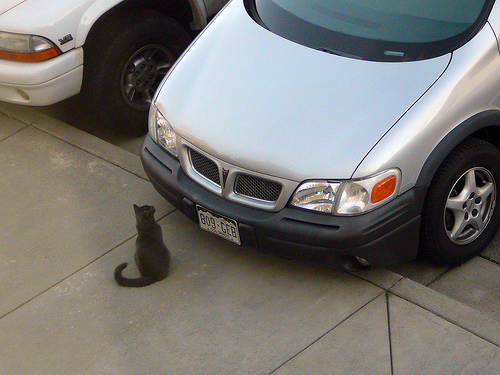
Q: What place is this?
A: It is a sidewalk.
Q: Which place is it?
A: It is a sidewalk.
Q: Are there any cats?
A: Yes, there is a cat.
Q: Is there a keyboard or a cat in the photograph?
A: Yes, there is a cat.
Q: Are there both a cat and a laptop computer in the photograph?
A: No, there is a cat but no laptops.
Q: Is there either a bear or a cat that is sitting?
A: Yes, the cat is sitting.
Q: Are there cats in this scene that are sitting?
A: Yes, there is a cat that is sitting.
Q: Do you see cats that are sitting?
A: Yes, there is a cat that is sitting.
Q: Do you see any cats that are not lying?
A: Yes, there is a cat that is sitting .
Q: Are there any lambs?
A: No, there are no lambs.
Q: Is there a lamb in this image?
A: No, there are no lambs.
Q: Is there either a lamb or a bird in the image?
A: No, there are no lambs or birds.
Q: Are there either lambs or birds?
A: No, there are no lambs or birds.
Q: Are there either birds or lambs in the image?
A: No, there are no lambs or birds.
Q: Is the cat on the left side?
A: Yes, the cat is on the left of the image.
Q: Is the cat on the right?
A: No, the cat is on the left of the image.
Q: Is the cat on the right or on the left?
A: The cat is on the left of the image.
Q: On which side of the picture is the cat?
A: The cat is on the left of the image.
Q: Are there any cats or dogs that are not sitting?
A: No, there is a cat but it is sitting.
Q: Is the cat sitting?
A: Yes, the cat is sitting.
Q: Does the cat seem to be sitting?
A: Yes, the cat is sitting.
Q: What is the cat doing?
A: The cat is sitting.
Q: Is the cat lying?
A: No, the cat is sitting.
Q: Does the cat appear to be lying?
A: No, the cat is sitting.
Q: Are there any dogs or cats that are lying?
A: No, there is a cat but it is sitting.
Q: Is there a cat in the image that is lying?
A: No, there is a cat but it is sitting.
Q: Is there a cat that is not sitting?
A: No, there is a cat but it is sitting.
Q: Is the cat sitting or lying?
A: The cat is sitting.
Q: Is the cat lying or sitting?
A: The cat is sitting.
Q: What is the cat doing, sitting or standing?
A: The cat is sitting.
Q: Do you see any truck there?
A: No, there are no trucks.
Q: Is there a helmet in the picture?
A: No, there are no helmets.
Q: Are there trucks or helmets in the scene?
A: No, there are no helmets or trucks.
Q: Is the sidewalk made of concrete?
A: Yes, the sidewalk is made of concrete.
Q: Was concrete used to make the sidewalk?
A: Yes, the sidewalk is made of concrete.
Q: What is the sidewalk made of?
A: The sidewalk is made of concrete.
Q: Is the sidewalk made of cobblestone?
A: No, the sidewalk is made of cement.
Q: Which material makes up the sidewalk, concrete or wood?
A: The sidewalk is made of concrete.